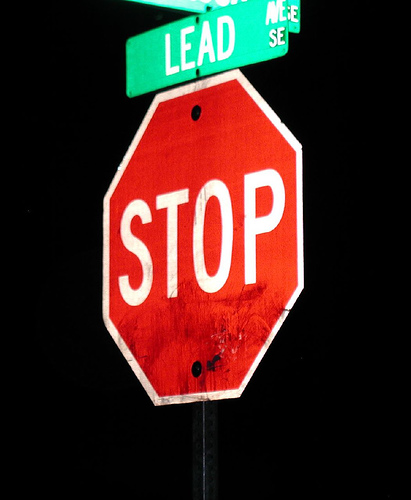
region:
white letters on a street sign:
[159, 12, 233, 74]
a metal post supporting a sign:
[183, 399, 215, 490]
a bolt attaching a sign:
[182, 354, 197, 368]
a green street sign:
[121, 0, 287, 93]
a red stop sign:
[91, 103, 318, 407]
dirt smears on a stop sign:
[120, 278, 290, 395]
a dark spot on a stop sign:
[201, 351, 223, 371]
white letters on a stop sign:
[114, 159, 291, 316]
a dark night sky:
[2, 2, 406, 494]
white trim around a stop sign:
[91, 77, 319, 407]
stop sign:
[86, 80, 314, 357]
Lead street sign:
[262, 24, 290, 48]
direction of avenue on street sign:
[259, 25, 293, 49]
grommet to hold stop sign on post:
[180, 353, 215, 382]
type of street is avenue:
[259, 0, 293, 21]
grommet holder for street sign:
[188, 64, 202, 74]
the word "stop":
[112, 164, 284, 303]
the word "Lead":
[156, 17, 240, 65]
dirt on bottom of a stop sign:
[93, 275, 296, 407]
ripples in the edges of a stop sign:
[234, 70, 327, 151]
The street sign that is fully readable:
[120, 0, 291, 99]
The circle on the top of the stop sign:
[184, 101, 200, 121]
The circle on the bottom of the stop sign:
[185, 354, 201, 378]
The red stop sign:
[83, 66, 307, 408]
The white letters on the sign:
[113, 163, 283, 307]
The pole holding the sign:
[190, 394, 219, 499]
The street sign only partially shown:
[122, 0, 303, 35]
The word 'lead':
[160, 15, 238, 77]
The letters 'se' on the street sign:
[267, 26, 285, 48]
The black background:
[1, 1, 409, 498]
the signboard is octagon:
[74, 75, 408, 419]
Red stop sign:
[88, 85, 316, 407]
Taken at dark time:
[273, 342, 409, 460]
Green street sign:
[102, 0, 313, 92]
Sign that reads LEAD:
[112, 5, 297, 95]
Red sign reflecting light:
[76, 93, 342, 415]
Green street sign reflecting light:
[110, 1, 306, 101]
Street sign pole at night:
[148, 383, 247, 498]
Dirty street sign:
[83, 66, 332, 406]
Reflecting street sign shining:
[108, 0, 316, 102]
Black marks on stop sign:
[105, 288, 315, 427]